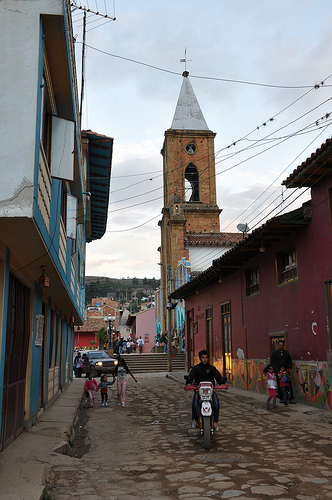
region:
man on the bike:
[190, 350, 222, 436]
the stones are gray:
[135, 377, 182, 426]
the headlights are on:
[95, 358, 121, 367]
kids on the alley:
[83, 364, 119, 420]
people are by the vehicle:
[72, 345, 118, 377]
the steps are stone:
[117, 348, 176, 383]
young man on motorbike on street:
[182, 350, 229, 451]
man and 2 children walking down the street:
[261, 338, 294, 411]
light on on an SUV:
[72, 348, 119, 378]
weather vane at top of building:
[178, 46, 193, 76]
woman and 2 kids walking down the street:
[82, 355, 141, 408]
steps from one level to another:
[109, 352, 187, 374]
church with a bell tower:
[157, 49, 223, 348]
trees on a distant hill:
[85, 275, 161, 303]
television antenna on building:
[66, 0, 116, 144]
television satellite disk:
[235, 222, 250, 237]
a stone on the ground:
[211, 479, 232, 494]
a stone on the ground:
[189, 461, 205, 470]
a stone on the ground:
[248, 486, 283, 498]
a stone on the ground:
[177, 484, 206, 498]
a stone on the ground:
[258, 464, 286, 480]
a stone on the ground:
[291, 467, 324, 485]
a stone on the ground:
[150, 464, 166, 474]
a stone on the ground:
[137, 469, 163, 477]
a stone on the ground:
[181, 437, 194, 443]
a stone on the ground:
[249, 437, 263, 444]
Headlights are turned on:
[88, 354, 121, 369]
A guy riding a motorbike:
[176, 344, 230, 451]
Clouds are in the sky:
[63, 0, 326, 277]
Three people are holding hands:
[79, 347, 139, 407]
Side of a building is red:
[178, 168, 325, 382]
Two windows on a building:
[239, 238, 298, 297]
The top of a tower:
[159, 39, 214, 131]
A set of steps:
[113, 345, 188, 375]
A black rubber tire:
[194, 407, 215, 449]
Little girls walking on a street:
[84, 370, 113, 405]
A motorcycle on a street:
[187, 381, 225, 444]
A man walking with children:
[257, 337, 300, 408]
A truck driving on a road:
[77, 350, 115, 375]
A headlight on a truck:
[95, 360, 104, 367]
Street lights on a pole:
[105, 313, 113, 347]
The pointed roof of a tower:
[171, 68, 204, 125]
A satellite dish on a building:
[236, 222, 249, 232]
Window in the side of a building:
[272, 243, 297, 286]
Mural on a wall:
[291, 366, 330, 404]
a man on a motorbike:
[179, 347, 238, 448]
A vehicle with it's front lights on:
[71, 347, 119, 378]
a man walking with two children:
[261, 336, 303, 412]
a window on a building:
[276, 250, 294, 277]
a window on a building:
[221, 308, 239, 382]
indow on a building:
[200, 315, 211, 369]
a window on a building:
[185, 320, 194, 366]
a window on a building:
[52, 313, 57, 365]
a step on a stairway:
[110, 350, 183, 356]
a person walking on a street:
[272, 335, 297, 408]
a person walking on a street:
[258, 362, 281, 406]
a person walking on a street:
[110, 355, 138, 407]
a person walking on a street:
[97, 370, 118, 406]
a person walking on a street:
[79, 373, 101, 414]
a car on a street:
[73, 347, 114, 377]